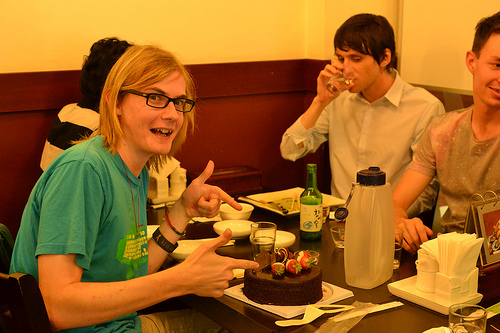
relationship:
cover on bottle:
[356, 161, 388, 190] [348, 188, 375, 282]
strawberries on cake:
[271, 250, 312, 279] [240, 245, 332, 309]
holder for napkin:
[431, 266, 484, 303] [422, 231, 490, 273]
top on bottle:
[354, 165, 386, 185] [342, 167, 396, 290]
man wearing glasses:
[11, 44, 258, 329] [117, 86, 195, 111]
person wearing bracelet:
[39, 37, 134, 180] [153, 227, 178, 253]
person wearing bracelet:
[39, 37, 134, 180] [163, 212, 185, 236]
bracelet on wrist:
[153, 227, 178, 253] [152, 197, 190, 254]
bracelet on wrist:
[163, 212, 185, 236] [152, 197, 190, 254]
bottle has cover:
[342, 167, 396, 290] [355, 166, 385, 186]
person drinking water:
[290, 10, 466, 197] [328, 70, 346, 93]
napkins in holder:
[417, 228, 485, 280] [434, 267, 479, 304]